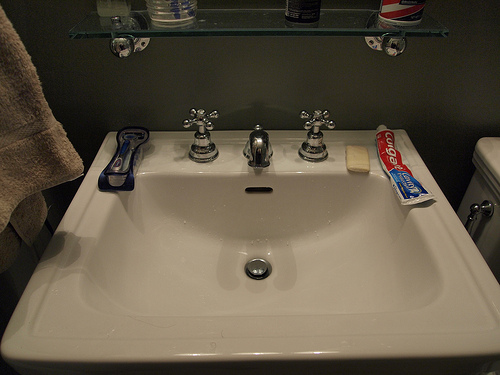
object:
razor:
[99, 126, 149, 189]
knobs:
[182, 105, 220, 163]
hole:
[244, 186, 273, 194]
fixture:
[241, 122, 275, 168]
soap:
[345, 142, 371, 173]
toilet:
[461, 132, 498, 264]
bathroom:
[17, 15, 496, 358]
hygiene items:
[375, 124, 437, 207]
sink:
[18, 170, 496, 352]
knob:
[299, 108, 336, 162]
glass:
[144, 1, 196, 29]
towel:
[1, 0, 92, 260]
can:
[378, 0, 425, 27]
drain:
[243, 257, 273, 281]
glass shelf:
[75, 15, 470, 39]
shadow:
[40, 229, 84, 285]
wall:
[0, 12, 108, 306]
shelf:
[67, 8, 462, 59]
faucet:
[182, 107, 335, 168]